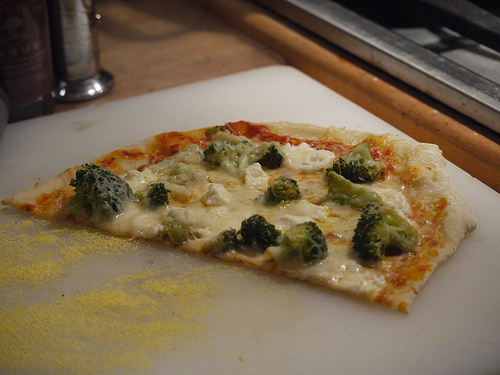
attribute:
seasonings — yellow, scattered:
[3, 212, 221, 374]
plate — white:
[2, 64, 499, 374]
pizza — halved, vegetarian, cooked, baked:
[19, 112, 471, 314]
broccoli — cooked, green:
[71, 124, 414, 274]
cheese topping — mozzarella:
[81, 138, 412, 302]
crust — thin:
[12, 112, 478, 316]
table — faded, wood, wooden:
[5, 2, 499, 367]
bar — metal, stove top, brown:
[291, 1, 500, 115]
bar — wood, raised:
[217, 6, 494, 157]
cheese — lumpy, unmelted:
[276, 138, 334, 173]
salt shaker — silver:
[49, 2, 115, 105]